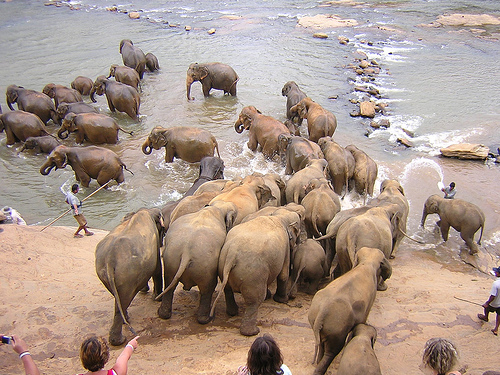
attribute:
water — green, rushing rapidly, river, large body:
[1, 0, 500, 277]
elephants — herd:
[2, 39, 485, 374]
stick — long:
[42, 178, 113, 231]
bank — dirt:
[1, 224, 500, 375]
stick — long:
[453, 296, 482, 308]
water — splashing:
[401, 158, 444, 182]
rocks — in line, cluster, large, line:
[338, 35, 390, 138]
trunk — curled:
[142, 138, 152, 155]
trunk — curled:
[40, 160, 55, 176]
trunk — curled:
[58, 126, 69, 139]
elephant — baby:
[145, 53, 160, 72]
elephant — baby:
[18, 135, 60, 155]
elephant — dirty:
[95, 208, 165, 344]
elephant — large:
[217, 210, 303, 336]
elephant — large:
[155, 201, 238, 324]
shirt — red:
[76, 369, 116, 374]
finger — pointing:
[133, 335, 140, 340]